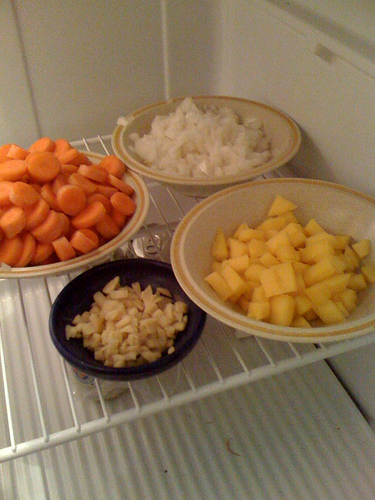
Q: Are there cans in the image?
A: Yes, there is a can.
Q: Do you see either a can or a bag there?
A: Yes, there is a can.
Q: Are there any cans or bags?
A: Yes, there is a can.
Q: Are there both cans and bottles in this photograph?
A: No, there is a can but no bottles.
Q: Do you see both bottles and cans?
A: No, there is a can but no bottles.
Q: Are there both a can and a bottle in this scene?
A: No, there is a can but no bottles.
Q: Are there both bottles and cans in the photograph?
A: No, there is a can but no bottles.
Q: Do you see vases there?
A: No, there are no vases.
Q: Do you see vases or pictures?
A: No, there are no vases or pictures.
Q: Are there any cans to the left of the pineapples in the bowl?
A: Yes, there is a can to the left of the pineapples.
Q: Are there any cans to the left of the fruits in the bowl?
A: Yes, there is a can to the left of the pineapples.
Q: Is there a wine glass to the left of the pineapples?
A: No, there is a can to the left of the pineapples.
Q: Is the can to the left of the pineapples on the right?
A: Yes, the can is to the left of the pineapples.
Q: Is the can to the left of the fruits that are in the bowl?
A: Yes, the can is to the left of the pineapples.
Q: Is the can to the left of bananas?
A: No, the can is to the left of the pineapples.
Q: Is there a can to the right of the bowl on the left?
A: Yes, there is a can to the right of the bowl.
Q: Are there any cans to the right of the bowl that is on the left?
A: Yes, there is a can to the right of the bowl.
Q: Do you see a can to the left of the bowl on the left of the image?
A: No, the can is to the right of the bowl.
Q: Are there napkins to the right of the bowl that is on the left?
A: No, there is a can to the right of the bowl.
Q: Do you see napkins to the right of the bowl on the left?
A: No, there is a can to the right of the bowl.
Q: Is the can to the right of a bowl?
A: Yes, the can is to the right of a bowl.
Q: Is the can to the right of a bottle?
A: No, the can is to the right of a bowl.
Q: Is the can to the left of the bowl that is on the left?
A: No, the can is to the right of the bowl.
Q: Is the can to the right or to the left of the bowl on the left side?
A: The can is to the right of the bowl.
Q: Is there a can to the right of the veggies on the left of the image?
A: Yes, there is a can to the right of the carrots.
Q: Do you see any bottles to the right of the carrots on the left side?
A: No, there is a can to the right of the carrots.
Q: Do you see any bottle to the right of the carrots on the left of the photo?
A: No, there is a can to the right of the carrots.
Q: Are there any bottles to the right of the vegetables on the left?
A: No, there is a can to the right of the carrots.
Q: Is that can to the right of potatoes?
A: No, the can is to the right of the carrots.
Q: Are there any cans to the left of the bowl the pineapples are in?
A: Yes, there is a can to the left of the bowl.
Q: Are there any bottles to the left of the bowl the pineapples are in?
A: No, there is a can to the left of the bowl.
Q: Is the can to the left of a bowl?
A: Yes, the can is to the left of a bowl.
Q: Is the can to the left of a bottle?
A: No, the can is to the left of a bowl.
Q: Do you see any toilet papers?
A: No, there are no toilet papers.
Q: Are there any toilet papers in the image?
A: No, there are no toilet papers.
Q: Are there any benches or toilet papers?
A: No, there are no toilet papers or benches.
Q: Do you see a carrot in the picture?
A: Yes, there are carrots.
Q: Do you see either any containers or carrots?
A: Yes, there are carrots.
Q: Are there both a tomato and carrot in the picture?
A: No, there are carrots but no tomatoes.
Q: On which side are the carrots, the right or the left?
A: The carrots are on the left of the image.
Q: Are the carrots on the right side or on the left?
A: The carrots are on the left of the image.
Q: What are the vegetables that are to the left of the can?
A: The vegetables are carrots.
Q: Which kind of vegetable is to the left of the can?
A: The vegetables are carrots.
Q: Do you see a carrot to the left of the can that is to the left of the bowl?
A: Yes, there are carrots to the left of the can.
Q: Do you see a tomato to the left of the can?
A: No, there are carrots to the left of the can.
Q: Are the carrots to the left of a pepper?
A: No, the carrots are to the left of the can.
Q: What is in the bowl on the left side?
A: The carrots are in the bowl.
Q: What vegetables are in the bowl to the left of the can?
A: The vegetables are carrots.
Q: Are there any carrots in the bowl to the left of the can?
A: Yes, there are carrots in the bowl.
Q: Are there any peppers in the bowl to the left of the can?
A: No, there are carrots in the bowl.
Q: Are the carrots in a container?
A: No, the carrots are in the bowl.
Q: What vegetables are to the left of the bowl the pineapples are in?
A: The vegetables are carrots.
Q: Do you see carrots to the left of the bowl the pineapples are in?
A: Yes, there are carrots to the left of the bowl.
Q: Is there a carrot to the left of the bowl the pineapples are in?
A: Yes, there are carrots to the left of the bowl.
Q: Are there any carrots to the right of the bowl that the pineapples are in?
A: No, the carrots are to the left of the bowl.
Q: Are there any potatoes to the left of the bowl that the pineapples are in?
A: No, there are carrots to the left of the bowl.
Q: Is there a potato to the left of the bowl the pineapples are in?
A: No, there are carrots to the left of the bowl.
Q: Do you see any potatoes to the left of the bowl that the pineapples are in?
A: No, there are carrots to the left of the bowl.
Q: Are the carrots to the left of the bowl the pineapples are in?
A: Yes, the carrots are to the left of the bowl.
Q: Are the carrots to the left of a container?
A: No, the carrots are to the left of the bowl.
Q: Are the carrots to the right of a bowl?
A: No, the carrots are to the left of a bowl.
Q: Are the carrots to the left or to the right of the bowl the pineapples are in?
A: The carrots are to the left of the bowl.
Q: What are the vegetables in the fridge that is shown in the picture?
A: The vegetables are carrots.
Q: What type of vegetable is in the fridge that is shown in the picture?
A: The vegetables are carrots.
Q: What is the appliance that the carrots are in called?
A: The appliance is a refrigerator.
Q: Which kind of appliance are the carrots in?
A: The carrots are in the freezer.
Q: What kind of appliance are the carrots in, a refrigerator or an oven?
A: The carrots are in a refrigerator.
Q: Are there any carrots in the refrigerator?
A: Yes, there are carrots in the refrigerator.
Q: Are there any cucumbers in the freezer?
A: No, there are carrots in the freezer.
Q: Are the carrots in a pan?
A: No, the carrots are in the refrigerator.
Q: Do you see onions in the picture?
A: Yes, there are onions.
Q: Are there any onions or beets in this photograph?
A: Yes, there are onions.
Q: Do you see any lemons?
A: No, there are no lemons.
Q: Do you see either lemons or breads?
A: No, there are no lemons or breads.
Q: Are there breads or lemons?
A: No, there are no lemons or breads.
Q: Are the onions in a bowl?
A: Yes, the onions are in a bowl.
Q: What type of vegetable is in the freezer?
A: The vegetables are onions.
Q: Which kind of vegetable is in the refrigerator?
A: The vegetables are onions.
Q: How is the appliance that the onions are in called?
A: The appliance is a refrigerator.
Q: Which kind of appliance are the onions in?
A: The onions are in the fridge.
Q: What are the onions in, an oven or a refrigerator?
A: The onions are in a refrigerator.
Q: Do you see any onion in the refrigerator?
A: Yes, there are onions in the refrigerator.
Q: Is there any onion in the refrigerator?
A: Yes, there are onions in the refrigerator.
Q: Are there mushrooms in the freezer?
A: No, there are onions in the freezer.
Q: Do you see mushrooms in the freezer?
A: No, there are onions in the freezer.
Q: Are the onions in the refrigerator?
A: Yes, the onions are in the refrigerator.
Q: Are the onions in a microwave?
A: No, the onions are in the refrigerator.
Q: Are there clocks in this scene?
A: No, there are no clocks.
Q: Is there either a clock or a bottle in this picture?
A: No, there are no clocks or bottles.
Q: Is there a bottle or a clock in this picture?
A: No, there are no clocks or bottles.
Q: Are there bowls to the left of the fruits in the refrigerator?
A: Yes, there is a bowl to the left of the pineapples.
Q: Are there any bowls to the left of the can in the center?
A: Yes, there is a bowl to the left of the can.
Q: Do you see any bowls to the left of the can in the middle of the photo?
A: Yes, there is a bowl to the left of the can.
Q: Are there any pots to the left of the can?
A: No, there is a bowl to the left of the can.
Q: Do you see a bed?
A: No, there are no beds.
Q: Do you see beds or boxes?
A: No, there are no beds or boxes.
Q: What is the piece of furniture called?
A: The piece of furniture is a shelf.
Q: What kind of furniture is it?
A: The piece of furniture is a shelf.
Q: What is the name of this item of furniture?
A: This is a shelf.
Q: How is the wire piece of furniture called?
A: The piece of furniture is a shelf.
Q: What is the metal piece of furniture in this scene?
A: The piece of furniture is a shelf.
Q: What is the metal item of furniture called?
A: The piece of furniture is a shelf.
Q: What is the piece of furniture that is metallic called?
A: The piece of furniture is a shelf.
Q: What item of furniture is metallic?
A: The piece of furniture is a shelf.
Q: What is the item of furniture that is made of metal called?
A: The piece of furniture is a shelf.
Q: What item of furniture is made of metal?
A: The piece of furniture is a shelf.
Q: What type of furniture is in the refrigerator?
A: The piece of furniture is a shelf.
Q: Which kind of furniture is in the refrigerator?
A: The piece of furniture is a shelf.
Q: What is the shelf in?
A: The shelf is in the fridge.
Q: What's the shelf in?
A: The shelf is in the fridge.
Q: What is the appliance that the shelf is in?
A: The appliance is a refrigerator.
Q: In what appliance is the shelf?
A: The shelf is in the freezer.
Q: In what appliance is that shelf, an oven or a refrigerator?
A: The shelf is in a refrigerator.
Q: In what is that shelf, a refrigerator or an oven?
A: The shelf is in a refrigerator.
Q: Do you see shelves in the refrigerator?
A: Yes, there is a shelf in the refrigerator.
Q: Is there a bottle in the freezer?
A: No, there is a shelf in the freezer.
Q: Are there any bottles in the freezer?
A: No, there is a shelf in the freezer.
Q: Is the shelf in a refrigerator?
A: Yes, the shelf is in a refrigerator.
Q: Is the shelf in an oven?
A: No, the shelf is in a refrigerator.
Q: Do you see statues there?
A: No, there are no statues.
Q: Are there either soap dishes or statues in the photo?
A: No, there are no statues or soap dishes.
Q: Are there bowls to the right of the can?
A: Yes, there is a bowl to the right of the can.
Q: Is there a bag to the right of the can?
A: No, there is a bowl to the right of the can.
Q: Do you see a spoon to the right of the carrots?
A: No, there is a bowl to the right of the carrots.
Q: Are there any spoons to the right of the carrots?
A: No, there is a bowl to the right of the carrots.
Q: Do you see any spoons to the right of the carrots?
A: No, there is a bowl to the right of the carrots.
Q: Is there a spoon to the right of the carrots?
A: No, there is a bowl to the right of the carrots.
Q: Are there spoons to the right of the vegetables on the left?
A: No, there is a bowl to the right of the carrots.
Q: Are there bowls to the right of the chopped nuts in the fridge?
A: Yes, there is a bowl to the right of the nuts.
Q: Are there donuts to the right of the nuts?
A: No, there is a bowl to the right of the nuts.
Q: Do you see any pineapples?
A: Yes, there are pineapples.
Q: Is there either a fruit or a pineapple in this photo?
A: Yes, there are pineapples.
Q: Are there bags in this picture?
A: No, there are no bags.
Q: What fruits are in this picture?
A: The fruits are pineapples.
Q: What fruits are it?
A: The fruits are pineapples.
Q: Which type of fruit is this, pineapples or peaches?
A: These are pineapples.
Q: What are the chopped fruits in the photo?
A: The fruits are pineapples.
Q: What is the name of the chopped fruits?
A: The fruits are pineapples.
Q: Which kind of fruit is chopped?
A: The fruit is pineapples.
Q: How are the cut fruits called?
A: The fruits are pineapples.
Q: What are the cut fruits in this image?
A: The fruits are pineapples.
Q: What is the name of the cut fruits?
A: The fruits are pineapples.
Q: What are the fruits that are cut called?
A: The fruits are pineapples.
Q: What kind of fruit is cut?
A: The fruit is pineapples.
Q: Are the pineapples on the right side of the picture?
A: Yes, the pineapples are on the right of the image.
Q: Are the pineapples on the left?
A: No, the pineapples are on the right of the image.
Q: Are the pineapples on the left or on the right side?
A: The pineapples are on the right of the image.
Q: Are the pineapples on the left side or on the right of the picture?
A: The pineapples are on the right of the image.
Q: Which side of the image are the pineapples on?
A: The pineapples are on the right of the image.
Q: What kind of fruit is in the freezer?
A: The fruits are pineapples.